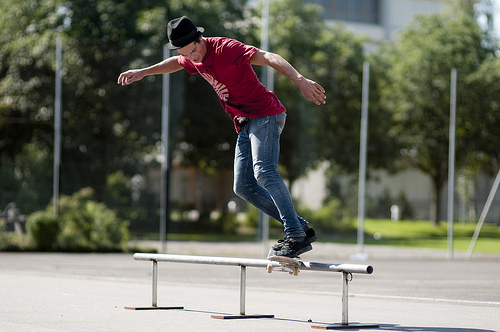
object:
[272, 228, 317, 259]
footwear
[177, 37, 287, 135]
shirt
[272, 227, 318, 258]
black shoes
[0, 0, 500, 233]
tree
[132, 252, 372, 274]
tube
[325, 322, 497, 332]
shadow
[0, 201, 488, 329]
ground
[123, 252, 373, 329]
metal rail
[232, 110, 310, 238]
blue jeans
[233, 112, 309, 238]
pants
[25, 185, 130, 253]
bush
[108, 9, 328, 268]
boarder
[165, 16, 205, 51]
black hat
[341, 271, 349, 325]
pole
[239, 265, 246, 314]
pole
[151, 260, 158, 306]
pole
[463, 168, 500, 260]
pole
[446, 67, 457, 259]
pole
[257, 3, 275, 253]
pole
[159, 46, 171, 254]
pole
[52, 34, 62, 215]
pole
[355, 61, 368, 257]
metal pole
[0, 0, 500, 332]
park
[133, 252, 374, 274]
pole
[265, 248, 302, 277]
skateboard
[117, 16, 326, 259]
male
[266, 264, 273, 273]
wheel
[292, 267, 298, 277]
wheel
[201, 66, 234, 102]
design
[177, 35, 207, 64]
head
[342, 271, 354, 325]
stand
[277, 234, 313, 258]
man's feet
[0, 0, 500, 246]
background